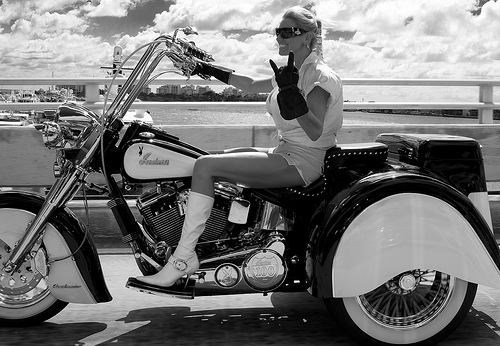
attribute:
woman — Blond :
[138, 3, 344, 291]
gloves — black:
[263, 60, 324, 124]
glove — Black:
[261, 54, 340, 125]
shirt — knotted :
[260, 47, 348, 150]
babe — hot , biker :
[137, 2, 344, 287]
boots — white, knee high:
[133, 192, 214, 289]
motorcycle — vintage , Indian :
[1, 25, 498, 345]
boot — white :
[136, 190, 214, 289]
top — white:
[257, 52, 342, 150]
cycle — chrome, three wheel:
[2, 24, 498, 344]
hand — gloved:
[268, 54, 308, 118]